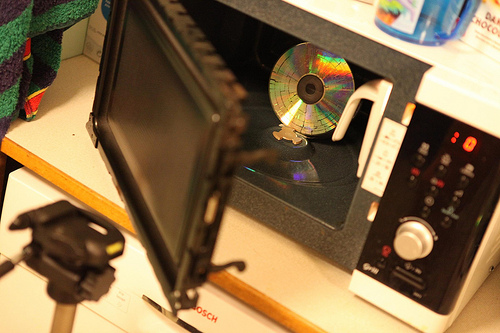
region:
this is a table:
[59, 75, 80, 170]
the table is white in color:
[56, 67, 88, 122]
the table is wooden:
[38, 131, 74, 179]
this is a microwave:
[100, 6, 477, 303]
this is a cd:
[263, 36, 358, 138]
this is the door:
[98, 9, 227, 313]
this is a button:
[392, 215, 427, 269]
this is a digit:
[447, 127, 477, 150]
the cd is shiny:
[287, 46, 336, 133]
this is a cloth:
[5, 1, 40, 97]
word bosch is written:
[203, 305, 211, 314]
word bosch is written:
[205, 312, 222, 325]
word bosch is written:
[199, 303, 216, 329]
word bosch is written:
[201, 307, 213, 317]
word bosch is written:
[193, 302, 206, 312]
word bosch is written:
[195, 308, 226, 324]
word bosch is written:
[193, 295, 210, 311]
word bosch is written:
[193, 310, 218, 321]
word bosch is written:
[195, 304, 197, 306]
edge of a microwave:
[182, 178, 229, 283]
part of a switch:
[386, 227, 417, 264]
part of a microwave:
[371, 253, 414, 306]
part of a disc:
[288, 111, 322, 150]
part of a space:
[296, 71, 333, 105]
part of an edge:
[258, 276, 291, 320]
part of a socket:
[43, 233, 98, 328]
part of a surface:
[304, 152, 339, 182]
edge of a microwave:
[284, 211, 328, 256]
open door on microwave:
[91, 13, 491, 319]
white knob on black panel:
[375, 100, 490, 311]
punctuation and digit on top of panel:
[402, 110, 497, 165]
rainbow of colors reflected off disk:
[262, 30, 352, 140]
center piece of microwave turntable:
[266, 115, 301, 150]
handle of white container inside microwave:
[320, 71, 391, 177]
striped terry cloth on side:
[2, 5, 87, 146]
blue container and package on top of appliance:
[365, 0, 495, 55]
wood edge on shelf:
[12, 125, 307, 325]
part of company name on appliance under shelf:
[35, 280, 250, 327]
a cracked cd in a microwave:
[266, 35, 353, 142]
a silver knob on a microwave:
[390, 220, 436, 264]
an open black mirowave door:
[76, 2, 270, 298]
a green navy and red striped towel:
[0, 0, 101, 142]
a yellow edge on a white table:
[0, 135, 326, 332]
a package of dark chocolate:
[460, 2, 498, 56]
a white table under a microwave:
[4, 54, 498, 331]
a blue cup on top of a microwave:
[373, 0, 486, 48]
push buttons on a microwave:
[400, 127, 485, 227]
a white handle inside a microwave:
[326, 65, 402, 187]